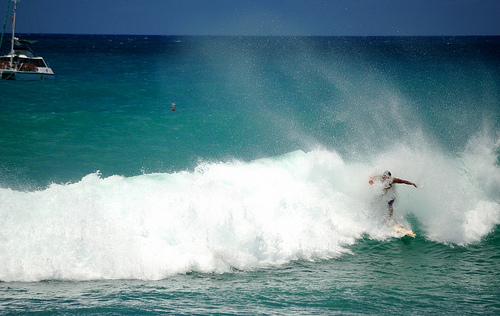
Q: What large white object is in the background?
A: Sail boat.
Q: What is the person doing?
A: Surfing.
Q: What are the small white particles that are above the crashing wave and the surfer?
A: Sea spray.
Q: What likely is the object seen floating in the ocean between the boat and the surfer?
A: A buoy.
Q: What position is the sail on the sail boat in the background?
A: Down.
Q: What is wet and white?
A: Surfer.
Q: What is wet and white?
A: Surfer.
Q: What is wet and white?
A: Surfer.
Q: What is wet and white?
A: Wurfer.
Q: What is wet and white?
A: Surfer.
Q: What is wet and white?
A: Surfer.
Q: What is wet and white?
A: Surfer.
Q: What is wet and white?
A: Surfer.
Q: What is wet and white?
A: Surfer.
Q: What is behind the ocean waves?
A: The spray of the water.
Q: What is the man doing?
A: Surfing.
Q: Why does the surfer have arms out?
A: To hold balance.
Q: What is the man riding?
A: A wave.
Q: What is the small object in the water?
A: Buoy.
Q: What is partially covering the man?
A: Waves.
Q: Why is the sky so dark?
A: Nightime.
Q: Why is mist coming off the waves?
A: Crashing waves.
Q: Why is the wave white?
A: Wave turbalance.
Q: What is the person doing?
A: Surfing.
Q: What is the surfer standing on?
A: Surf board.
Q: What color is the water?
A: Turquoise.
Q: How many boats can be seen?
A: One.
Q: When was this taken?
A: During the day.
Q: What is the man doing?
A: Surfing.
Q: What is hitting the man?
A: A wave.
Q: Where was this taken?
A: On the beach.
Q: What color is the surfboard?
A: White.